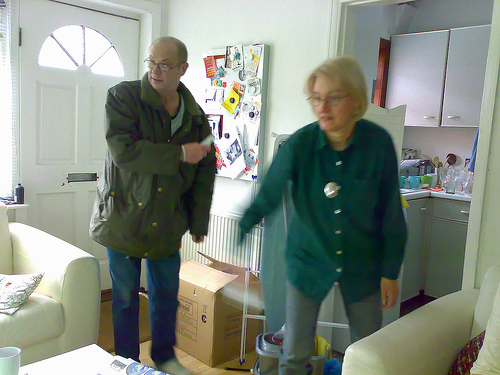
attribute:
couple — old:
[104, 26, 406, 343]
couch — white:
[1, 203, 100, 368]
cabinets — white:
[423, 197, 481, 369]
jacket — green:
[90, 77, 216, 262]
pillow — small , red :
[0, 261, 85, 351]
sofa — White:
[1, 212, 103, 370]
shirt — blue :
[234, 120, 407, 303]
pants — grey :
[278, 281, 384, 373]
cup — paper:
[6, 322, 34, 372]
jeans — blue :
[104, 257, 179, 354]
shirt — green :
[245, 129, 402, 298]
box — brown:
[175, 247, 259, 365]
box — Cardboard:
[165, 247, 264, 369]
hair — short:
[294, 32, 385, 117]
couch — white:
[319, 279, 493, 373]